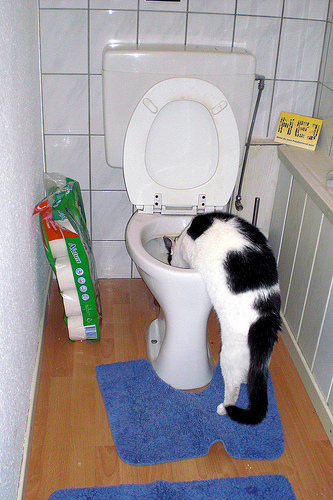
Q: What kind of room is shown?
A: It is a bathroom.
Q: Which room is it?
A: It is a bathroom.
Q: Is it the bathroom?
A: Yes, it is the bathroom.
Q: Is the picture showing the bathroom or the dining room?
A: It is showing the bathroom.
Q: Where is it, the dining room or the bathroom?
A: It is the bathroom.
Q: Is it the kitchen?
A: No, it is the bathroom.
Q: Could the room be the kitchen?
A: No, it is the bathroom.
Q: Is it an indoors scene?
A: Yes, it is indoors.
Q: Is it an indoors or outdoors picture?
A: It is indoors.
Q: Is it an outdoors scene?
A: No, it is indoors.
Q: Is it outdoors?
A: No, it is indoors.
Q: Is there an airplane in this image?
A: No, there are no airplanes.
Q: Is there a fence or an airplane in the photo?
A: No, there are no airplanes or fences.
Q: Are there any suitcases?
A: No, there are no suitcases.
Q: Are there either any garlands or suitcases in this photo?
A: No, there are no suitcases or garlands.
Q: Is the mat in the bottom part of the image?
A: Yes, the mat is in the bottom of the image.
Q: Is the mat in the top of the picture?
A: No, the mat is in the bottom of the image.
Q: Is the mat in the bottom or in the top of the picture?
A: The mat is in the bottom of the image.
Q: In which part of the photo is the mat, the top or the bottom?
A: The mat is in the bottom of the image.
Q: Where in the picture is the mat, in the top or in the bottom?
A: The mat is in the bottom of the image.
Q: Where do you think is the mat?
A: The mat is on the floor.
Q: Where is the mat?
A: The mat is on the floor.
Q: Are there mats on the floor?
A: Yes, there is a mat on the floor.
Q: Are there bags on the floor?
A: No, there is a mat on the floor.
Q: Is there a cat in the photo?
A: Yes, there is a cat.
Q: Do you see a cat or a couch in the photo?
A: Yes, there is a cat.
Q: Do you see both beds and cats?
A: No, there is a cat but no beds.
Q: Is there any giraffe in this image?
A: No, there are no giraffes.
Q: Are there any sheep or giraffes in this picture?
A: No, there are no giraffes or sheep.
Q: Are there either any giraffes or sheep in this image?
A: No, there are no giraffes or sheep.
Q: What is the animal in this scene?
A: The animal is a cat.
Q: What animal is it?
A: The animal is a cat.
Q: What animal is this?
A: This is a cat.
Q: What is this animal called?
A: This is a cat.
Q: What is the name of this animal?
A: This is a cat.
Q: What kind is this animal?
A: This is a cat.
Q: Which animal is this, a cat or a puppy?
A: This is a cat.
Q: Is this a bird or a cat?
A: This is a cat.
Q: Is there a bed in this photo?
A: No, there are no beds.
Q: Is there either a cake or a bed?
A: No, there are no beds or cakes.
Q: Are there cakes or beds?
A: No, there are no beds or cakes.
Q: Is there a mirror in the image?
A: No, there are no mirrors.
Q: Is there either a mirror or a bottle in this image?
A: No, there are no mirrors or bottles.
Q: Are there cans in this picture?
A: No, there are no cans.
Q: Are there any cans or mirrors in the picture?
A: No, there are no cans or mirrors.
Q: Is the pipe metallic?
A: Yes, the pipe is metallic.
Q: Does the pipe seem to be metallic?
A: Yes, the pipe is metallic.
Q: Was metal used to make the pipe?
A: Yes, the pipe is made of metal.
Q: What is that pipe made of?
A: The pipe is made of metal.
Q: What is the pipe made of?
A: The pipe is made of metal.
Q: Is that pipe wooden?
A: No, the pipe is metallic.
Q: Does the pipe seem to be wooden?
A: No, the pipe is metallic.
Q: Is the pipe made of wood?
A: No, the pipe is made of metal.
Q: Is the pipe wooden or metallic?
A: The pipe is metallic.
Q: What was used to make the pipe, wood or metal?
A: The pipe is made of metal.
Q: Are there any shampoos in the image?
A: No, there are no shampoos.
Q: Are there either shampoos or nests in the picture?
A: No, there are no shampoos or nests.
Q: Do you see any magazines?
A: No, there are no magazines.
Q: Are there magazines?
A: No, there are no magazines.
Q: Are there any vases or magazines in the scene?
A: No, there are no magazines or vases.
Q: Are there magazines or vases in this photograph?
A: No, there are no magazines or vases.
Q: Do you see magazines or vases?
A: No, there are no magazines or vases.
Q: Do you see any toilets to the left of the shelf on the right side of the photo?
A: Yes, there is a toilet to the left of the shelf.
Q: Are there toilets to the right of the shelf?
A: No, the toilet is to the left of the shelf.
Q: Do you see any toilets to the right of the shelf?
A: No, the toilet is to the left of the shelf.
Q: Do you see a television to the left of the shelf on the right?
A: No, there is a toilet to the left of the shelf.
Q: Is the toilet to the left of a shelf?
A: Yes, the toilet is to the left of a shelf.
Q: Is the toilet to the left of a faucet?
A: No, the toilet is to the left of a shelf.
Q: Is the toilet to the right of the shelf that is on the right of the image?
A: No, the toilet is to the left of the shelf.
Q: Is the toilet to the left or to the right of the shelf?
A: The toilet is to the left of the shelf.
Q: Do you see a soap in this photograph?
A: No, there are no soaps.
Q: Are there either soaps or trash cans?
A: No, there are no soaps or trash cans.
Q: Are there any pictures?
A: No, there are no pictures.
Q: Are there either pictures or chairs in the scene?
A: No, there are no pictures or chairs.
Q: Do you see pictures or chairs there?
A: No, there are no pictures or chairs.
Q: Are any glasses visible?
A: No, there are no glasses.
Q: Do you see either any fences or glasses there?
A: No, there are no glasses or fences.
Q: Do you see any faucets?
A: No, there are no faucets.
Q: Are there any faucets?
A: No, there are no faucets.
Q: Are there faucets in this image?
A: No, there are no faucets.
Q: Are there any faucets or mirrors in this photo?
A: No, there are no faucets or mirrors.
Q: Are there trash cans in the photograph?
A: No, there are no trash cans.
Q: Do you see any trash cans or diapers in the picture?
A: No, there are no trash cans or diapers.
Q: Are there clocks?
A: No, there are no clocks.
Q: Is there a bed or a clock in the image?
A: No, there are no clocks or beds.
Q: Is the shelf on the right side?
A: Yes, the shelf is on the right of the image.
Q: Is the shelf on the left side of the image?
A: No, the shelf is on the right of the image.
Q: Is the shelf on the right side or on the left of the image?
A: The shelf is on the right of the image.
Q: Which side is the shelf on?
A: The shelf is on the right of the image.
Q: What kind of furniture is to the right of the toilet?
A: The piece of furniture is a shelf.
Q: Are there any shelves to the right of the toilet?
A: Yes, there is a shelf to the right of the toilet.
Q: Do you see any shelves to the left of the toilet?
A: No, the shelf is to the right of the toilet.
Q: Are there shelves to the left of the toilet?
A: No, the shelf is to the right of the toilet.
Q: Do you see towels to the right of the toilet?
A: No, there is a shelf to the right of the toilet.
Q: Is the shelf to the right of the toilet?
A: Yes, the shelf is to the right of the toilet.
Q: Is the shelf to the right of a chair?
A: No, the shelf is to the right of the toilet.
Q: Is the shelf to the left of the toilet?
A: No, the shelf is to the right of the toilet.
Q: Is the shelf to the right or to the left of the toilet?
A: The shelf is to the right of the toilet.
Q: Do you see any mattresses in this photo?
A: No, there are no mattresses.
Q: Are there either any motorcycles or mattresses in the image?
A: No, there are no mattresses or motorcycles.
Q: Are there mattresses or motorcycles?
A: No, there are no mattresses or motorcycles.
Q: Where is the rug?
A: The rug is on the floor.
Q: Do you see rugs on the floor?
A: Yes, there is a rug on the floor.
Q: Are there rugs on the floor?
A: Yes, there is a rug on the floor.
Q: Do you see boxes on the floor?
A: No, there is a rug on the floor.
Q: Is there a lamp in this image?
A: No, there are no lamps.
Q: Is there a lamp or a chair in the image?
A: No, there are no lamps or chairs.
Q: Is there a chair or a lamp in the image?
A: No, there are no lamps or chairs.